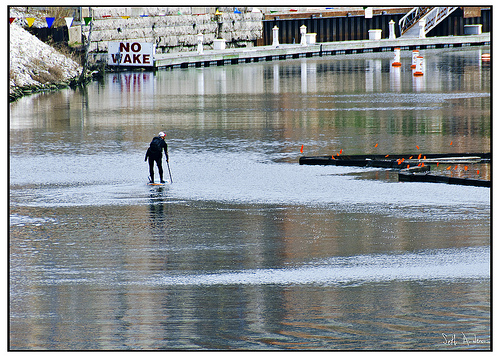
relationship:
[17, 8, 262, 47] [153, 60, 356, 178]
flags hanging above water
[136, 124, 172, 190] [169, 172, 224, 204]
man on water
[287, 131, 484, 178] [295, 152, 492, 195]
orange flags on divider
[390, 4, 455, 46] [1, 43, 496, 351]
ramp to water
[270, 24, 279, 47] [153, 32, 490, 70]
post on dock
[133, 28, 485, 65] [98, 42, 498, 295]
walk way on water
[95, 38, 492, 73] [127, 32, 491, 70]
edging on walkway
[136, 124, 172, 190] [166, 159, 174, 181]
man holding stick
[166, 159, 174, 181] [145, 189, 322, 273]
stick in water.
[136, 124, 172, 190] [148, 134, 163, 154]
man carrying a backpack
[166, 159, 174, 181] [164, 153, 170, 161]
stick in hand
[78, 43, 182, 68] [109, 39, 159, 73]
sign saying no wake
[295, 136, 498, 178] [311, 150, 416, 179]
flags along border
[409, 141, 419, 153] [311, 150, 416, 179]
flag along border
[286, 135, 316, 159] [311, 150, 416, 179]
flag along border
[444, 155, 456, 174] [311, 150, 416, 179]
flag along border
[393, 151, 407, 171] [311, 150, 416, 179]
flag along border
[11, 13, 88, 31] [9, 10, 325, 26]
colored flags on a rope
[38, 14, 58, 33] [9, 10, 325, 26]
flag on a rope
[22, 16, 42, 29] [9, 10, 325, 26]
flag on a rope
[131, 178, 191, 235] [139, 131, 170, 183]
reflection of a man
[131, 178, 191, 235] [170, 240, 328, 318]
reflection on water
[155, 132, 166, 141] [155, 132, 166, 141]
hat on hat